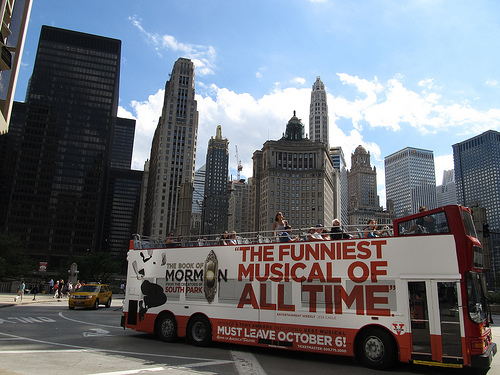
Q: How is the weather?
A: It is clear.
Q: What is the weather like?
A: It is clear.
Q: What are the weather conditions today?
A: It is clear.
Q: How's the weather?
A: It is clear.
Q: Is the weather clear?
A: Yes, it is clear.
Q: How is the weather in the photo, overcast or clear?
A: It is clear.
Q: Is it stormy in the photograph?
A: No, it is clear.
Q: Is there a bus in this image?
A: Yes, there is a bus.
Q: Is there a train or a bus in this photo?
A: Yes, there is a bus.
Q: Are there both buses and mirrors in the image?
A: No, there is a bus but no mirrors.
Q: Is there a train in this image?
A: No, there are no trains.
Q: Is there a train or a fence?
A: No, there are no trains or fences.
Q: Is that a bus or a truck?
A: That is a bus.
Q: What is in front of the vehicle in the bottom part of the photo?
A: The bus is in front of the taxi cab.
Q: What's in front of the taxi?
A: The bus is in front of the taxi cab.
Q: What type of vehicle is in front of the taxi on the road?
A: The vehicle is a bus.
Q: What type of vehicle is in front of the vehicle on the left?
A: The vehicle is a bus.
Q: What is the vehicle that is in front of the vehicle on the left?
A: The vehicle is a bus.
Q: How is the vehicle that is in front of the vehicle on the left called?
A: The vehicle is a bus.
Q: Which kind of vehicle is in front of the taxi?
A: The vehicle is a bus.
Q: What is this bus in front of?
A: The bus is in front of the cab.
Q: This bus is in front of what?
A: The bus is in front of the cab.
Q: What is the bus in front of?
A: The bus is in front of the cab.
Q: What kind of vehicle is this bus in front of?
A: The bus is in front of the taxi.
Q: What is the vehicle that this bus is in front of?
A: The vehicle is a taxi.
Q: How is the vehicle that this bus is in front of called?
A: The vehicle is a taxi.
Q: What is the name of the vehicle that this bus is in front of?
A: The vehicle is a taxi.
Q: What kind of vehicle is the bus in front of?
A: The bus is in front of the taxi.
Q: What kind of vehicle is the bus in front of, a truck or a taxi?
A: The bus is in front of a taxi.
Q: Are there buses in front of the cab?
A: Yes, there is a bus in front of the cab.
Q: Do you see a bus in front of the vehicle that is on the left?
A: Yes, there is a bus in front of the cab.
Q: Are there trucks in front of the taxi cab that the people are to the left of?
A: No, there is a bus in front of the taxi.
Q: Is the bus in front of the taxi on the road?
A: Yes, the bus is in front of the taxi.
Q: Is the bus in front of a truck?
A: No, the bus is in front of the taxi.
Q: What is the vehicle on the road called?
A: The vehicle is a bus.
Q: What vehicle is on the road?
A: The vehicle is a bus.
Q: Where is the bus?
A: The bus is on the road.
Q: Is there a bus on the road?
A: Yes, there is a bus on the road.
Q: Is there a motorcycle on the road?
A: No, there is a bus on the road.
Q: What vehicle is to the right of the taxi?
A: The vehicle is a bus.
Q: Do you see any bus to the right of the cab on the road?
A: Yes, there is a bus to the right of the taxi.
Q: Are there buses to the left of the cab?
A: No, the bus is to the right of the cab.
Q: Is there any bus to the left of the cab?
A: No, the bus is to the right of the cab.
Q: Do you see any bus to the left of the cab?
A: No, the bus is to the right of the cab.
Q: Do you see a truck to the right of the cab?
A: No, there is a bus to the right of the cab.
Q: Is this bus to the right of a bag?
A: No, the bus is to the right of the cab.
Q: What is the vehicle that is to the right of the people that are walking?
A: The vehicle is a bus.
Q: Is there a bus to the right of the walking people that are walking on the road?
A: Yes, there is a bus to the right of the people.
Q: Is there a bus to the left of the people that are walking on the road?
A: No, the bus is to the right of the people.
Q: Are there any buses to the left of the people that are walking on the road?
A: No, the bus is to the right of the people.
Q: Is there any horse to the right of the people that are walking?
A: No, there is a bus to the right of the people.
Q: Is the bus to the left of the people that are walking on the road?
A: No, the bus is to the right of the people.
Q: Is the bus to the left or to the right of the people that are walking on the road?
A: The bus is to the right of the people.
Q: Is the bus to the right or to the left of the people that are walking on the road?
A: The bus is to the right of the people.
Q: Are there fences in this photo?
A: No, there are no fences.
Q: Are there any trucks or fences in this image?
A: No, there are no fences or trucks.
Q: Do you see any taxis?
A: Yes, there is a taxi.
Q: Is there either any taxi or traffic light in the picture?
A: Yes, there is a taxi.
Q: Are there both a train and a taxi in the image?
A: No, there is a taxi but no trains.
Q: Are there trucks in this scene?
A: No, there are no trucks.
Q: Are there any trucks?
A: No, there are no trucks.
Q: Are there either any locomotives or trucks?
A: No, there are no trucks or locomotives.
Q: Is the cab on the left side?
A: Yes, the cab is on the left of the image.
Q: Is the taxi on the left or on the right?
A: The taxi is on the left of the image.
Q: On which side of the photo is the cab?
A: The cab is on the left of the image.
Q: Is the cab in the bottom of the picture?
A: Yes, the cab is in the bottom of the image.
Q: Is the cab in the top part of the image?
A: No, the cab is in the bottom of the image.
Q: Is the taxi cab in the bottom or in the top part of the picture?
A: The taxi cab is in the bottom of the image.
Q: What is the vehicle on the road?
A: The vehicle is a taxi.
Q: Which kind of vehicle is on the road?
A: The vehicle is a taxi.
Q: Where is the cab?
A: The cab is on the road.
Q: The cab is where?
A: The cab is on the road.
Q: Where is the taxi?
A: The cab is on the road.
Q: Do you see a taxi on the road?
A: Yes, there is a taxi on the road.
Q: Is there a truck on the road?
A: No, there is a taxi on the road.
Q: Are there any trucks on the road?
A: No, there is a taxi on the road.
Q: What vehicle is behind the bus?
A: The vehicle is a taxi.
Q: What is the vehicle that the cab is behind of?
A: The vehicle is a bus.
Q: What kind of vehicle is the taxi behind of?
A: The cab is behind the bus.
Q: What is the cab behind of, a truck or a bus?
A: The cab is behind a bus.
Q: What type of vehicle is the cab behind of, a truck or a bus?
A: The cab is behind a bus.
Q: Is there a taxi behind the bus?
A: Yes, there is a taxi behind the bus.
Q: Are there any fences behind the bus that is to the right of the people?
A: No, there is a taxi behind the bus.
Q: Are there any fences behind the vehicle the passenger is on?
A: No, there is a taxi behind the bus.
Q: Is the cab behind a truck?
A: No, the cab is behind the bus.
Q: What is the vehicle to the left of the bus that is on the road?
A: The vehicle is a taxi.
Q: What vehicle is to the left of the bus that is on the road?
A: The vehicle is a taxi.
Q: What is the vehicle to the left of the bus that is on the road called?
A: The vehicle is a taxi.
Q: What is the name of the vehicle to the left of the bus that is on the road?
A: The vehicle is a taxi.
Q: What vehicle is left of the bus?
A: The vehicle is a taxi.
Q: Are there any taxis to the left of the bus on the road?
A: Yes, there is a taxi to the left of the bus.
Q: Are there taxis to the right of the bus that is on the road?
A: No, the taxi is to the left of the bus.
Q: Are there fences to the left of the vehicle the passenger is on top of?
A: No, there is a taxi to the left of the bus.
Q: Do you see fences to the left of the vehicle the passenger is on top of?
A: No, there is a taxi to the left of the bus.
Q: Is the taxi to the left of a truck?
A: No, the taxi is to the left of the bus.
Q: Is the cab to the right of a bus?
A: No, the cab is to the left of a bus.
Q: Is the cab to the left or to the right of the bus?
A: The cab is to the left of the bus.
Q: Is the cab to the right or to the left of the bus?
A: The cab is to the left of the bus.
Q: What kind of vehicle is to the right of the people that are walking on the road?
A: The vehicle is a taxi.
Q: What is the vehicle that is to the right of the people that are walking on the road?
A: The vehicle is a taxi.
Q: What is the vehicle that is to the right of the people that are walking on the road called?
A: The vehicle is a taxi.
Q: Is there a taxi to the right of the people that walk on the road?
A: Yes, there is a taxi to the right of the people.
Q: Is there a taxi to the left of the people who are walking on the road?
A: No, the taxi is to the right of the people.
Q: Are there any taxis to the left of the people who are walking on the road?
A: No, the taxi is to the right of the people.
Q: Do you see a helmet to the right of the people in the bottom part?
A: No, there is a taxi to the right of the people.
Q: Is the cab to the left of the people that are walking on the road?
A: No, the cab is to the right of the people.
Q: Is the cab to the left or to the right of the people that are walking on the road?
A: The cab is to the right of the people.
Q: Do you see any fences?
A: No, there are no fences.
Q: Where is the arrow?
A: The arrow is on the road.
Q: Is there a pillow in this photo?
A: No, there are no pillows.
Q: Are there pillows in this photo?
A: No, there are no pillows.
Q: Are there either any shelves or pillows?
A: No, there are no pillows or shelves.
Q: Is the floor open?
A: Yes, the floor is open.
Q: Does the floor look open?
A: Yes, the floor is open.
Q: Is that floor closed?
A: No, the floor is open.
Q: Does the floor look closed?
A: No, the floor is open.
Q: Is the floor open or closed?
A: The floor is open.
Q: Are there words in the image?
A: Yes, there are words.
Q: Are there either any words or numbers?
A: Yes, there are words.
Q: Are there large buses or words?
A: Yes, there are large words.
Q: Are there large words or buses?
A: Yes, there are large words.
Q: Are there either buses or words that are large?
A: Yes, the words are large.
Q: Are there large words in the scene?
A: Yes, there are large words.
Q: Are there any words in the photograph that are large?
A: Yes, there are words that are large.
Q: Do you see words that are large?
A: Yes, there are words that are large.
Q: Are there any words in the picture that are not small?
A: Yes, there are large words.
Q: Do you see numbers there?
A: No, there are no numbers.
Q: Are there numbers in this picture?
A: No, there are no numbers.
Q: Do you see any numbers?
A: No, there are no numbers.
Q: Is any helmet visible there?
A: No, there are no helmets.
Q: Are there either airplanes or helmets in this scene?
A: No, there are no helmets or airplanes.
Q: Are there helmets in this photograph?
A: No, there are no helmets.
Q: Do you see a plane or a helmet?
A: No, there are no helmets or airplanes.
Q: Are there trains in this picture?
A: No, there are no trains.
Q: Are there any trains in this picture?
A: No, there are no trains.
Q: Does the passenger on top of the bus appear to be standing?
A: Yes, the passenger is standing.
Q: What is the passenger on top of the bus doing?
A: The passenger is standing.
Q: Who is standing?
A: The passenger is standing.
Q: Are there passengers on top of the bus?
A: Yes, there is a passenger on top of the bus.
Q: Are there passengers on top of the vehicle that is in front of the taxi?
A: Yes, there is a passenger on top of the bus.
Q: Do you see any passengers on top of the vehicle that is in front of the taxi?
A: Yes, there is a passenger on top of the bus.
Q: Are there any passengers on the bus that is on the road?
A: Yes, there is a passenger on the bus.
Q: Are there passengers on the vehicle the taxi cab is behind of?
A: Yes, there is a passenger on the bus.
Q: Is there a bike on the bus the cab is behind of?
A: No, there is a passenger on the bus.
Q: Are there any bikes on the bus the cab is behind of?
A: No, there is a passenger on the bus.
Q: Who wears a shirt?
A: The passenger wears a shirt.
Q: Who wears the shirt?
A: The passenger wears a shirt.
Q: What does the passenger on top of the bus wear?
A: The passenger wears a shirt.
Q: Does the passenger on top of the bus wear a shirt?
A: Yes, the passenger wears a shirt.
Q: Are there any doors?
A: Yes, there is a door.